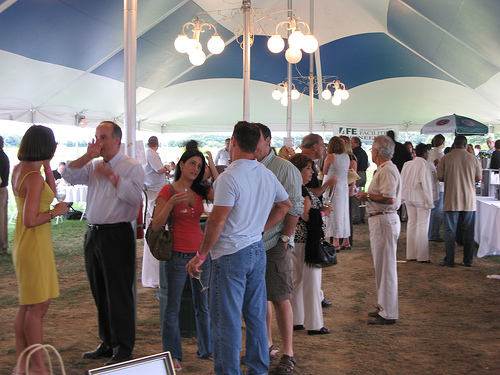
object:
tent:
[0, 0, 500, 139]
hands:
[82, 136, 106, 160]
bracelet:
[191, 249, 211, 264]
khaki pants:
[359, 211, 414, 318]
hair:
[370, 134, 398, 162]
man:
[435, 134, 483, 269]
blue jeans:
[202, 242, 275, 375]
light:
[263, 35, 292, 57]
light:
[320, 88, 333, 101]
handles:
[7, 340, 68, 373]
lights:
[202, 32, 230, 59]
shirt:
[154, 182, 209, 253]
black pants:
[75, 216, 138, 351]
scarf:
[304, 208, 328, 266]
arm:
[304, 192, 332, 221]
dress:
[9, 163, 66, 308]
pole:
[119, 3, 145, 171]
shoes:
[78, 337, 111, 358]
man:
[241, 121, 308, 375]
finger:
[174, 198, 186, 204]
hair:
[172, 147, 218, 209]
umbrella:
[419, 111, 491, 136]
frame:
[84, 344, 176, 374]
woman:
[146, 148, 222, 373]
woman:
[7, 125, 69, 373]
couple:
[1, 118, 149, 375]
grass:
[0, 201, 85, 301]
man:
[55, 114, 150, 362]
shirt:
[55, 152, 146, 229]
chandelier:
[261, 33, 286, 56]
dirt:
[0, 208, 500, 373]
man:
[185, 118, 293, 374]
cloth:
[473, 197, 498, 262]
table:
[472, 192, 500, 259]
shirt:
[205, 156, 290, 262]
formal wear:
[363, 158, 401, 320]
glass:
[185, 257, 210, 300]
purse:
[143, 183, 178, 264]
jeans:
[202, 243, 274, 373]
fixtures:
[174, 0, 227, 68]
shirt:
[261, 148, 308, 252]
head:
[177, 149, 206, 181]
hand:
[180, 251, 208, 278]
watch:
[365, 192, 372, 202]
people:
[353, 134, 401, 327]